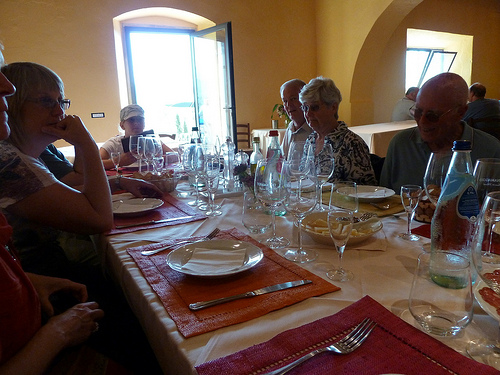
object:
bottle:
[430, 140, 485, 289]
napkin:
[176, 248, 248, 274]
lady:
[298, 75, 375, 192]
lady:
[0, 61, 115, 302]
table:
[104, 165, 500, 375]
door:
[121, 22, 239, 159]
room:
[0, 0, 500, 375]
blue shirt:
[377, 119, 499, 196]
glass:
[407, 250, 475, 340]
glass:
[397, 185, 421, 242]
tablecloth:
[97, 153, 500, 375]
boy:
[99, 104, 174, 162]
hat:
[119, 104, 145, 121]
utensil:
[187, 279, 313, 312]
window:
[404, 42, 456, 90]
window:
[123, 21, 244, 147]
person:
[280, 80, 313, 170]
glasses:
[408, 104, 455, 117]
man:
[381, 72, 500, 194]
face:
[412, 95, 460, 141]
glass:
[325, 210, 354, 282]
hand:
[50, 300, 104, 344]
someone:
[0, 214, 100, 375]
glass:
[278, 160, 321, 262]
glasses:
[22, 94, 69, 111]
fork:
[260, 313, 380, 375]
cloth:
[191, 293, 500, 375]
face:
[299, 98, 335, 131]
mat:
[106, 151, 500, 339]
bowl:
[291, 205, 383, 248]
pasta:
[308, 214, 373, 236]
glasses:
[299, 104, 328, 111]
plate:
[164, 238, 264, 280]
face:
[17, 84, 66, 142]